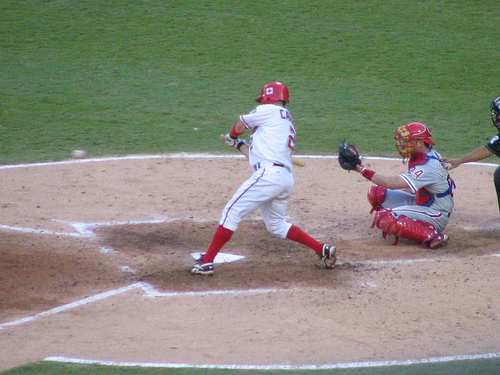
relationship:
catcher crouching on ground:
[333, 105, 466, 269] [1, 0, 498, 373]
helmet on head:
[397, 116, 439, 144] [391, 122, 439, 161]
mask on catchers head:
[392, 125, 416, 158] [396, 120, 434, 157]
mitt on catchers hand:
[330, 136, 360, 169] [338, 144, 362, 169]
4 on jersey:
[411, 169, 426, 180] [370, 147, 455, 232]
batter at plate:
[195, 74, 365, 274] [193, 249, 242, 267]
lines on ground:
[149, 265, 373, 307] [1, 0, 498, 373]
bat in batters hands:
[219, 132, 310, 172] [219, 130, 243, 149]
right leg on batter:
[189, 176, 273, 271] [186, 80, 335, 275]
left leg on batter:
[270, 200, 339, 265] [186, 80, 335, 275]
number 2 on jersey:
[411, 159, 418, 174] [242, 103, 297, 172]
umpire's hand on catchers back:
[439, 136, 492, 184] [412, 150, 452, 213]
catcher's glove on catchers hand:
[333, 135, 360, 174] [338, 140, 360, 172]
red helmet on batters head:
[253, 81, 290, 103] [259, 77, 291, 104]